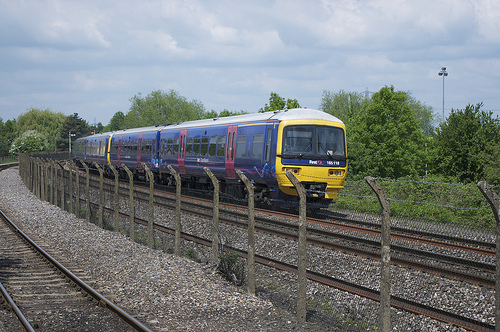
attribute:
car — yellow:
[160, 100, 350, 225]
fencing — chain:
[7, 142, 498, 332]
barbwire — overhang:
[375, 174, 479, 217]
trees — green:
[5, 97, 64, 167]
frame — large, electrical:
[355, 82, 377, 99]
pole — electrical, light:
[439, 75, 452, 117]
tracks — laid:
[7, 191, 157, 326]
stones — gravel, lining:
[153, 270, 201, 293]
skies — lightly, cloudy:
[5, 52, 498, 156]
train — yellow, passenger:
[67, 104, 349, 216]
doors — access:
[222, 121, 240, 179]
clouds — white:
[37, 18, 116, 57]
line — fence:
[14, 145, 484, 329]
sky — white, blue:
[85, 20, 341, 110]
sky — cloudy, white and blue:
[4, 1, 491, 125]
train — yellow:
[69, 118, 358, 205]